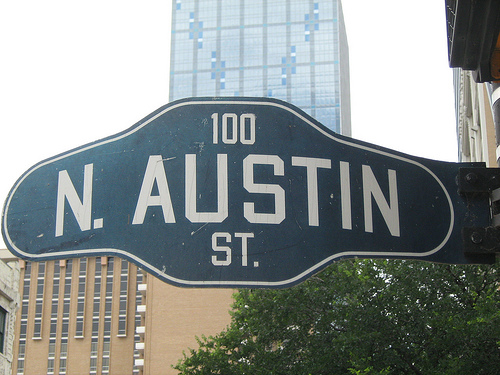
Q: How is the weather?
A: Sunny.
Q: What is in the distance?
A: Buildings.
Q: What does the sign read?
A: N austin.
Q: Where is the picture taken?
A: A street.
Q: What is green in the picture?
A: A tree.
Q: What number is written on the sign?
A: 100.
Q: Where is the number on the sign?
A: Top.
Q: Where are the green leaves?
A: Tree.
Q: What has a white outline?
A: Sign.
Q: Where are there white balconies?
A: Brown building.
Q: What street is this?
A: N. Austin St.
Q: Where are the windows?
A: On the buildings.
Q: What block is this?
A: The 100 block.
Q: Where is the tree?
A: On a city street.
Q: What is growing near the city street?
A: A tree.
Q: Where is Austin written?
A: On the street sign.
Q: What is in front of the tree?
A: A street sign.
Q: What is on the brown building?
A: Lots of windows.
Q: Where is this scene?
A: A city street.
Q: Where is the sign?
A: In front of the tree.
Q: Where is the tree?
A: Behind the sign.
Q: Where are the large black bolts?
A: On the sign.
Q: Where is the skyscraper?
A: Behind the sign.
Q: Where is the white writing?
A: On the sign.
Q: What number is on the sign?
A: 100.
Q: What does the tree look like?
A: Healthy.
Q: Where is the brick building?
A: In front of skyscraper.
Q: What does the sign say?
A: N. Austin ST.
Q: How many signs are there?
A: One.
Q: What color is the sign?
A: Black.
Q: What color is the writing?
A: White.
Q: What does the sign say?
A: 100 N. Austin St.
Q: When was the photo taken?
A: Daytime.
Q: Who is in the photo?
A: No one.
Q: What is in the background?
A: Buildings.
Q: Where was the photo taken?
A: N Austin Street.